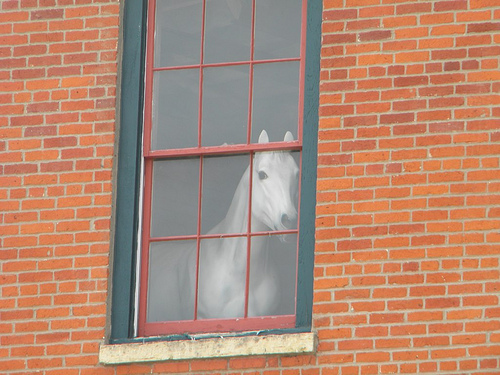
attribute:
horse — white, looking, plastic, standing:
[170, 124, 300, 320]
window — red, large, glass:
[93, 2, 325, 369]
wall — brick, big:
[2, 1, 496, 373]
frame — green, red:
[106, 0, 326, 349]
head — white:
[235, 125, 300, 253]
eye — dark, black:
[252, 164, 274, 188]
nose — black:
[278, 207, 297, 232]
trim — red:
[133, 1, 308, 335]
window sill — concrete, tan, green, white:
[95, 329, 323, 369]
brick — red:
[345, 66, 374, 81]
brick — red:
[379, 85, 423, 104]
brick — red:
[339, 135, 379, 156]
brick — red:
[21, 120, 61, 141]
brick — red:
[38, 157, 77, 177]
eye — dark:
[289, 166, 301, 184]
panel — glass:
[204, 66, 251, 146]